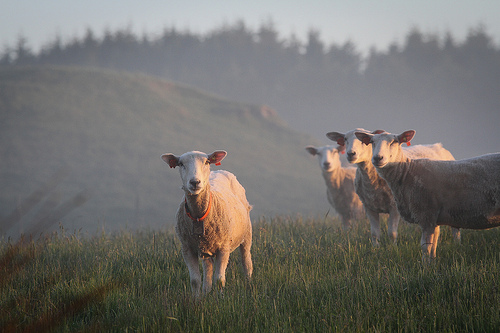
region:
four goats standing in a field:
[169, 14, 466, 297]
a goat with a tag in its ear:
[141, 132, 228, 211]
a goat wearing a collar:
[172, 142, 224, 235]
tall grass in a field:
[254, 274, 444, 332]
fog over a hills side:
[61, 49, 368, 159]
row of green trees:
[1, 24, 476, 101]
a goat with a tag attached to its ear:
[155, 132, 230, 229]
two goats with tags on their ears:
[316, 119, 412, 184]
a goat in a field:
[137, 124, 252, 304]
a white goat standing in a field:
[146, 119, 259, 281]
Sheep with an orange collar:
[162, 148, 255, 298]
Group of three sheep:
[306, 127, 496, 263]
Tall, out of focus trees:
[1, 15, 498, 157]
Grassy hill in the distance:
[1, 66, 337, 222]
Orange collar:
[180, 195, 215, 222]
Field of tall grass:
[1, 207, 498, 331]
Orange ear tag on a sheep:
[214, 156, 221, 166]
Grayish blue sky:
[0, 0, 498, 68]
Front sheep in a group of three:
[355, 130, 498, 257]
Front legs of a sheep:
[179, 242, 226, 296]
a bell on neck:
[182, 193, 214, 239]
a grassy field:
[2, 207, 497, 332]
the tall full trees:
[2, 19, 497, 158]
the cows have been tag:
[159, 120, 499, 293]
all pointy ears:
[162, 122, 417, 173]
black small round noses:
[183, 148, 405, 189]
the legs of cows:
[179, 214, 498, 298]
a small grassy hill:
[0, 60, 352, 237]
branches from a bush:
[0, 165, 135, 331]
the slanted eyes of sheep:
[175, 138, 403, 172]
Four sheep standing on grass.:
[159, 124, 493, 325]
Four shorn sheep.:
[160, 125, 490, 290]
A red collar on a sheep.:
[175, 190, 212, 226]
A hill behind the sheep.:
[5, 57, 341, 232]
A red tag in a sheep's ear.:
[205, 145, 228, 170]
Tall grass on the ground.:
[0, 210, 485, 325]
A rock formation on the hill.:
[225, 90, 284, 125]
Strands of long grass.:
[5, 151, 135, 326]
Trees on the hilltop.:
[0, 10, 495, 70]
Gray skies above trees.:
[5, 2, 496, 42]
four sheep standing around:
[140, 87, 499, 274]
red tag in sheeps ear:
[213, 157, 220, 174]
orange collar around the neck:
[168, 179, 233, 244]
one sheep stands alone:
[110, 120, 281, 302]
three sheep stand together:
[297, 102, 498, 273]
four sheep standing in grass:
[127, 95, 499, 310]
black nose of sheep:
[188, 173, 208, 187]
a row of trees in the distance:
[32, 20, 497, 133]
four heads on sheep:
[149, 98, 413, 200]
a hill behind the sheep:
[11, 50, 368, 217]